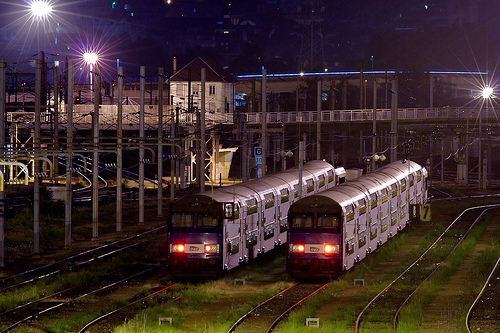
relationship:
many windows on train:
[345, 170, 422, 225] [284, 160, 433, 276]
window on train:
[261, 193, 276, 211] [163, 158, 340, 282]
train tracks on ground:
[1, 183, 497, 330] [4, 176, 497, 332]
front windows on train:
[171, 215, 220, 232] [163, 158, 340, 282]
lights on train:
[164, 240, 338, 257] [281, 159, 427, 282]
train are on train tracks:
[281, 159, 427, 282] [1, 183, 497, 330]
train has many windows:
[284, 160, 433, 276] [345, 170, 427, 224]